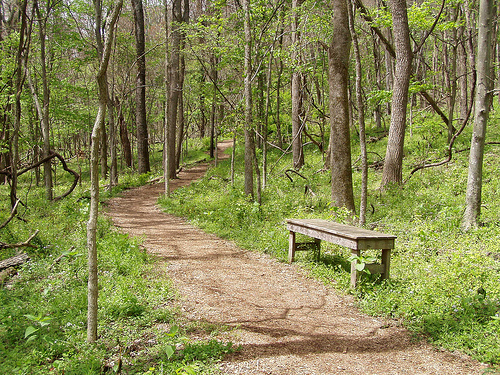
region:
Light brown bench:
[277, 207, 394, 287]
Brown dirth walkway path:
[139, 243, 345, 370]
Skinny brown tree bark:
[75, 125, 112, 352]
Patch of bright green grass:
[114, 294, 194, 364]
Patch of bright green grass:
[413, 258, 465, 311]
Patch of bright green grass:
[14, 299, 64, 351]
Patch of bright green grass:
[194, 189, 246, 209]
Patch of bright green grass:
[39, 212, 79, 242]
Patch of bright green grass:
[45, 358, 122, 368]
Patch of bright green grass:
[432, 310, 484, 351]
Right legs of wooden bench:
[280, 231, 326, 266]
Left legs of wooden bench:
[338, 247, 397, 289]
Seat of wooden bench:
[283, 204, 400, 258]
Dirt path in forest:
[92, 131, 488, 373]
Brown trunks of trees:
[0, 0, 487, 351]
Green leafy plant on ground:
[15, 302, 62, 357]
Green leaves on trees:
[171, 7, 447, 114]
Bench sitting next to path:
[272, 209, 405, 295]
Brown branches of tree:
[0, 194, 47, 261]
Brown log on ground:
[0, 249, 40, 284]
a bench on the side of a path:
[281, 214, 397, 292]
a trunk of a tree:
[323, 36, 358, 204]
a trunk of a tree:
[382, 26, 412, 194]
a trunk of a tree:
[461, 67, 487, 234]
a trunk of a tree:
[131, 42, 149, 175]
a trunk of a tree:
[82, 122, 107, 342]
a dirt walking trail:
[107, 212, 259, 294]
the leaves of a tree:
[193, 23, 231, 53]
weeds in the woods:
[395, 199, 456, 244]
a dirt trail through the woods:
[9, 15, 280, 189]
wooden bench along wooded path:
[284, 215, 397, 290]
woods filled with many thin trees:
[0, 0, 499, 374]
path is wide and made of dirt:
[102, 138, 487, 374]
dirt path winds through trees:
[104, 136, 496, 373]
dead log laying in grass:
[0, 251, 32, 267]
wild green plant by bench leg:
[348, 250, 373, 280]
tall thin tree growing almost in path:
[162, 0, 173, 198]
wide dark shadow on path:
[221, 324, 468, 361]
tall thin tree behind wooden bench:
[347, 0, 369, 226]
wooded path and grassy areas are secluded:
[0, 0, 498, 374]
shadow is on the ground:
[246, 291, 357, 366]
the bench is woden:
[286, 218, 415, 296]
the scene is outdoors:
[17, 8, 478, 370]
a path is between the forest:
[130, 201, 297, 360]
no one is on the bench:
[282, 216, 408, 298]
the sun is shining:
[3, 9, 490, 373]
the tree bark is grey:
[188, 34, 476, 172]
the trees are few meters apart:
[61, 83, 473, 192]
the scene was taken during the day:
[18, 17, 472, 374]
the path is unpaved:
[126, 199, 306, 326]